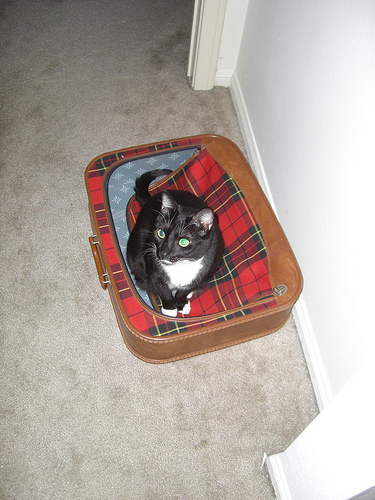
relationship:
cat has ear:
[124, 160, 228, 317] [190, 207, 215, 239]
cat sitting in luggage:
[124, 160, 228, 317] [83, 126, 305, 365]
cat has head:
[124, 160, 228, 317] [148, 194, 219, 263]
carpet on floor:
[0, 1, 258, 497] [15, 18, 323, 380]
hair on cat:
[175, 195, 204, 310] [118, 158, 225, 331]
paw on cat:
[159, 304, 178, 320] [124, 160, 228, 317]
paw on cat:
[177, 297, 191, 315] [124, 160, 228, 317]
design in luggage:
[109, 169, 125, 182] [82, 131, 306, 363]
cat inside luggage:
[124, 160, 228, 317] [82, 131, 306, 363]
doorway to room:
[184, 0, 228, 94] [0, 1, 193, 91]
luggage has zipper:
[73, 126, 311, 371] [199, 127, 224, 147]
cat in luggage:
[124, 160, 228, 317] [83, 126, 305, 365]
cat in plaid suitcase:
[137, 194, 214, 299] [89, 157, 288, 326]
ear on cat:
[190, 207, 215, 239] [124, 160, 228, 317]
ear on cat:
[159, 192, 178, 214] [124, 160, 228, 317]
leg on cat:
[150, 278, 179, 320] [124, 160, 228, 317]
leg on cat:
[170, 285, 193, 316] [124, 160, 228, 317]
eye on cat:
[154, 227, 168, 238] [124, 160, 228, 317]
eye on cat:
[174, 237, 193, 247] [124, 160, 228, 317]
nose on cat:
[157, 244, 169, 258] [124, 160, 228, 317]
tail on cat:
[131, 164, 176, 208] [124, 160, 228, 317]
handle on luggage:
[86, 231, 111, 292] [82, 131, 306, 363]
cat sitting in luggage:
[124, 160, 228, 317] [82, 131, 306, 363]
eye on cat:
[174, 237, 193, 247] [125, 162, 220, 326]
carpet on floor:
[40, 417, 258, 482] [30, 354, 184, 471]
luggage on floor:
[83, 126, 305, 365] [6, 5, 345, 497]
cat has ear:
[124, 160, 228, 317] [158, 189, 179, 215]